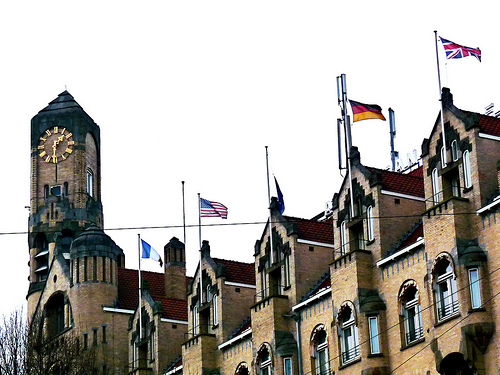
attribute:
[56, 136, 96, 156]
numerals — gold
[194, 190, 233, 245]
flag — french, red, white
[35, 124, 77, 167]
clock — bronze colored, metal, large, roman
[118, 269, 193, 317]
tiles — red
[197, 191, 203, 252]
pole — tall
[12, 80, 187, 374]
building — large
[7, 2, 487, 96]
sky — white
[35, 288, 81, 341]
window — big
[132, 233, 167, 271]
flag — blue, white